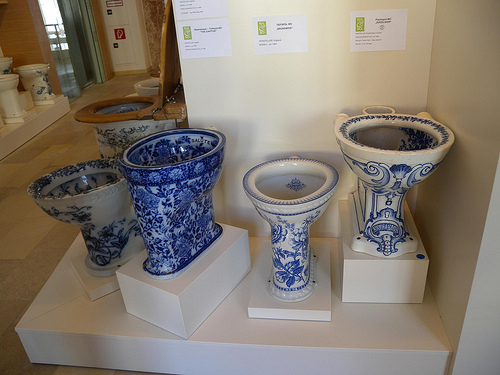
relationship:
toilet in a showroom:
[332, 101, 456, 261] [0, 0, 499, 374]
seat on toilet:
[72, 92, 160, 122] [77, 3, 180, 156]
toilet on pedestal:
[323, 101, 463, 260] [54, 230, 151, 316]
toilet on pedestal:
[242, 145, 351, 297] [109, 205, 256, 352]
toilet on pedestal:
[114, 125, 234, 282] [247, 222, 355, 344]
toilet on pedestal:
[30, 149, 160, 277] [334, 189, 444, 322]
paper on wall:
[250, 14, 311, 55] [188, 62, 423, 95]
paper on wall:
[347, 6, 409, 51] [174, 2, 438, 236]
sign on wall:
[111, 26, 129, 40] [102, 0, 147, 84]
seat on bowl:
[71, 96, 159, 124] [90, 101, 174, 160]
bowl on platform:
[25, 157, 131, 227] [65, 250, 120, 301]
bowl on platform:
[112, 126, 227, 206] [116, 220, 251, 337]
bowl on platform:
[241, 155, 339, 230] [249, 237, 332, 322]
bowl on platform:
[333, 111, 456, 194] [338, 198, 430, 303]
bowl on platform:
[333, 111, 456, 194] [11, 219, 432, 371]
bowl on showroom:
[332, 106, 455, 194] [0, 0, 497, 374]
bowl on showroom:
[241, 155, 340, 230] [0, 0, 497, 374]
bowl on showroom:
[116, 124, 226, 197] [0, 0, 497, 374]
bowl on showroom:
[25, 156, 131, 226] [0, 0, 497, 374]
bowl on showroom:
[91, 119, 177, 159] [0, 0, 497, 374]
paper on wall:
[172, 18, 233, 60] [202, 60, 269, 102]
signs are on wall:
[174, 7, 421, 87] [266, 67, 351, 108]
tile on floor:
[40, 138, 52, 159] [13, 217, 35, 281]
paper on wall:
[347, 6, 409, 51] [173, 0, 433, 255]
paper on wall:
[250, 14, 311, 55] [173, 0, 433, 255]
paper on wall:
[176, 18, 233, 60] [173, 0, 433, 255]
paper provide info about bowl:
[347, 6, 409, 51] [331, 104, 455, 259]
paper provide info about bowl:
[250, 14, 311, 55] [241, 154, 337, 302]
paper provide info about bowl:
[176, 18, 233, 60] [118, 126, 225, 278]